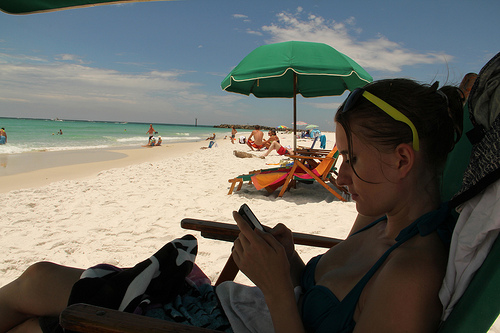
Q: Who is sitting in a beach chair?
A: A girl.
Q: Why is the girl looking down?
A: She is using her phone.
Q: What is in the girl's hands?
A: A cell phone.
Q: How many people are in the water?
A: Three.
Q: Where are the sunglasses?
A: On the girl's head.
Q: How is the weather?
A: Sunny.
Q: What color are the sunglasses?
A: Black and yellow.